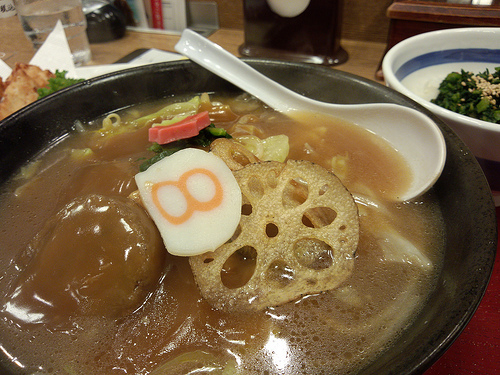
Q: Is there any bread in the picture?
A: Yes, there is a bread.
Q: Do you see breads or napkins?
A: Yes, there is a bread.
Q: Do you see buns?
A: No, there are no buns.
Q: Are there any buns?
A: No, there are no buns.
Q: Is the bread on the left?
A: Yes, the bread is on the left of the image.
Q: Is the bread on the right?
A: No, the bread is on the left of the image.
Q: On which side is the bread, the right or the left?
A: The bread is on the left of the image.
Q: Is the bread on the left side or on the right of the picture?
A: The bread is on the left of the image.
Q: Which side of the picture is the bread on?
A: The bread is on the left of the image.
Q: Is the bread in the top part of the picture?
A: Yes, the bread is in the top of the image.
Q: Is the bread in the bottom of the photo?
A: No, the bread is in the top of the image.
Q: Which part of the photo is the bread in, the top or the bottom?
A: The bread is in the top of the image.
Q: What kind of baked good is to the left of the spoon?
A: The food is a bread.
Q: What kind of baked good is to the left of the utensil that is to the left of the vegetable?
A: The food is a bread.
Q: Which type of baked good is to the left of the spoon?
A: The food is a bread.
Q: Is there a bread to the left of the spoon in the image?
A: Yes, there is a bread to the left of the spoon.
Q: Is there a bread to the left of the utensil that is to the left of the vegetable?
A: Yes, there is a bread to the left of the spoon.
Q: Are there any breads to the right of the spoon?
A: No, the bread is to the left of the spoon.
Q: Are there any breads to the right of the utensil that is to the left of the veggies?
A: No, the bread is to the left of the spoon.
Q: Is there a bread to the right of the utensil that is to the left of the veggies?
A: No, the bread is to the left of the spoon.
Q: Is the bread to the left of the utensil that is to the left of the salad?
A: Yes, the bread is to the left of the spoon.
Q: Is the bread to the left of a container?
A: No, the bread is to the left of the spoon.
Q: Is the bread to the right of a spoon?
A: No, the bread is to the left of a spoon.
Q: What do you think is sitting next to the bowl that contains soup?
A: The bread is sitting next to the bowl.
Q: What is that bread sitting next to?
A: The bread is sitting next to the bowl.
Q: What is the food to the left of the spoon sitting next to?
A: The bread is sitting next to the bowl.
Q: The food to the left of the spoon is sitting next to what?
A: The bread is sitting next to the bowl.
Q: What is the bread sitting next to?
A: The bread is sitting next to the bowl.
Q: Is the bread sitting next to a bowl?
A: Yes, the bread is sitting next to a bowl.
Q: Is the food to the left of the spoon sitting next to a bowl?
A: Yes, the bread is sitting next to a bowl.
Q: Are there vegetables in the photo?
A: Yes, there are vegetables.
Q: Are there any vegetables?
A: Yes, there are vegetables.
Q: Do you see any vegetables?
A: Yes, there are vegetables.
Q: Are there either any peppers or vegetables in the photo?
A: Yes, there are vegetables.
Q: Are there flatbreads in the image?
A: No, there are no flatbreads.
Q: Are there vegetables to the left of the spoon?
A: No, the vegetables are to the right of the spoon.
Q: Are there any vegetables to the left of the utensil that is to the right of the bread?
A: No, the vegetables are to the right of the spoon.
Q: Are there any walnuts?
A: No, there are no walnuts.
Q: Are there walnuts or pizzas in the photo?
A: No, there are no walnuts or pizzas.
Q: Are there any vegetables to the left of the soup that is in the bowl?
A: Yes, there is a vegetable to the left of the soup.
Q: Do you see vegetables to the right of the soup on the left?
A: Yes, there is a vegetable to the right of the soup.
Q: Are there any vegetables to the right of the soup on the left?
A: Yes, there is a vegetable to the right of the soup.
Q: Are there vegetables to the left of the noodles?
A: Yes, there is a vegetable to the left of the noodles.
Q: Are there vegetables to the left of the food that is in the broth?
A: Yes, there is a vegetable to the left of the noodles.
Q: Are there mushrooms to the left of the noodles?
A: No, there is a vegetable to the left of the noodles.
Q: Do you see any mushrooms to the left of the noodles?
A: No, there is a vegetable to the left of the noodles.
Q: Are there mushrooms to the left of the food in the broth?
A: No, there is a vegetable to the left of the noodles.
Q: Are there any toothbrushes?
A: No, there are no toothbrushes.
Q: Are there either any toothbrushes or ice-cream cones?
A: No, there are no toothbrushes or ice-cream cones.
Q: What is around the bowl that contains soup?
A: The ring is around the bowl.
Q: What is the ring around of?
A: The ring is around the bowl.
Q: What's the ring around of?
A: The ring is around the bowl.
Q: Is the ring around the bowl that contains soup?
A: Yes, the ring is around the bowl.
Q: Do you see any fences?
A: No, there are no fences.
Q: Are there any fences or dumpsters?
A: No, there are no fences or dumpsters.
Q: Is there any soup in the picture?
A: Yes, there is soup.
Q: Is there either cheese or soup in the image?
A: Yes, there is soup.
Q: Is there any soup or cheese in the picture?
A: Yes, there is soup.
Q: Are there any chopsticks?
A: No, there are no chopsticks.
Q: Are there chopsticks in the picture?
A: No, there are no chopsticks.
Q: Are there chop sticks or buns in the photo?
A: No, there are no chop sticks or buns.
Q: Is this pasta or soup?
A: This is soup.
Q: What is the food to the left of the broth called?
A: The food is soup.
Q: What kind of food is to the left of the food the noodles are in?
A: The food is soup.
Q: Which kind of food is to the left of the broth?
A: The food is soup.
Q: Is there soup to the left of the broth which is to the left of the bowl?
A: Yes, there is soup to the left of the broth.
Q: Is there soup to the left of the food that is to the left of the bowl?
A: Yes, there is soup to the left of the broth.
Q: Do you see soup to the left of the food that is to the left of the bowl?
A: Yes, there is soup to the left of the broth.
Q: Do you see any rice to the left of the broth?
A: No, there is soup to the left of the broth.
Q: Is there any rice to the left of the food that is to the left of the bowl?
A: No, there is soup to the left of the broth.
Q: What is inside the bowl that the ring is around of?
A: The soup is inside the bowl.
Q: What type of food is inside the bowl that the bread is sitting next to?
A: The food is soup.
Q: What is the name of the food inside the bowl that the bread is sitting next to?
A: The food is soup.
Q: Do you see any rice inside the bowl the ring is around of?
A: No, there is soup inside the bowl.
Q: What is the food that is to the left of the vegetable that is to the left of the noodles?
A: The food is soup.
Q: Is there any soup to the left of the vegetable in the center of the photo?
A: Yes, there is soup to the left of the vegetable.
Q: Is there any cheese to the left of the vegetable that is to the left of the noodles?
A: No, there is soup to the left of the vegetable.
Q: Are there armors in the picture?
A: No, there are no armors.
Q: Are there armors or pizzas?
A: No, there are no armors or pizzas.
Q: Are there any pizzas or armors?
A: No, there are no armors or pizzas.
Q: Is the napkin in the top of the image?
A: Yes, the napkin is in the top of the image.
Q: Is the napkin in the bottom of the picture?
A: No, the napkin is in the top of the image.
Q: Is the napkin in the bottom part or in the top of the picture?
A: The napkin is in the top of the image.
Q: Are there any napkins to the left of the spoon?
A: Yes, there is a napkin to the left of the spoon.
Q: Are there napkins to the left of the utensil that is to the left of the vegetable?
A: Yes, there is a napkin to the left of the spoon.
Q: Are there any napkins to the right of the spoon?
A: No, the napkin is to the left of the spoon.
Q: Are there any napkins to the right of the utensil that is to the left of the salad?
A: No, the napkin is to the left of the spoon.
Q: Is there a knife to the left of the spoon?
A: No, there is a napkin to the left of the spoon.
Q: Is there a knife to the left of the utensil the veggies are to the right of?
A: No, there is a napkin to the left of the spoon.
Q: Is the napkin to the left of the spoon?
A: Yes, the napkin is to the left of the spoon.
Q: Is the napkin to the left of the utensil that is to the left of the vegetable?
A: Yes, the napkin is to the left of the spoon.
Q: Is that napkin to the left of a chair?
A: No, the napkin is to the left of the spoon.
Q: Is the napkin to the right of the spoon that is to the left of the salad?
A: No, the napkin is to the left of the spoon.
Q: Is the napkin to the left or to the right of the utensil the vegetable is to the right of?
A: The napkin is to the left of the spoon.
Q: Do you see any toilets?
A: No, there are no toilets.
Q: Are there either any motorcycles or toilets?
A: No, there are no toilets or motorcycles.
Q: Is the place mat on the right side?
A: Yes, the place mat is on the right of the image.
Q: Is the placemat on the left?
A: No, the placemat is on the right of the image.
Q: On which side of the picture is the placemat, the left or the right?
A: The placemat is on the right of the image.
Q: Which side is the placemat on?
A: The placemat is on the right of the image.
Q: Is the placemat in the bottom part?
A: Yes, the placemat is in the bottom of the image.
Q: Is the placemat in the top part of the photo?
A: No, the placemat is in the bottom of the image.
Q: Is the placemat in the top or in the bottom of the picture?
A: The placemat is in the bottom of the image.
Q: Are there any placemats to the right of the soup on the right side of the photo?
A: Yes, there is a placemat to the right of the soup.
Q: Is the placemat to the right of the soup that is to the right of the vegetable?
A: Yes, the placemat is to the right of the soup.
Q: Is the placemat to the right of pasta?
A: No, the placemat is to the right of the soup.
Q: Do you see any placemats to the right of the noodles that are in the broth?
A: Yes, there is a placemat to the right of the noodles.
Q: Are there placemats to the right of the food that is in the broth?
A: Yes, there is a placemat to the right of the noodles.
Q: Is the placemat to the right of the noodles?
A: Yes, the placemat is to the right of the noodles.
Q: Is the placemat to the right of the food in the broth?
A: Yes, the placemat is to the right of the noodles.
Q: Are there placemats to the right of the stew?
A: Yes, there is a placemat to the right of the stew.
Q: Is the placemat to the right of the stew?
A: Yes, the placemat is to the right of the stew.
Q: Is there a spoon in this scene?
A: Yes, there is a spoon.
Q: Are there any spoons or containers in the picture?
A: Yes, there is a spoon.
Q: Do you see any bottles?
A: No, there are no bottles.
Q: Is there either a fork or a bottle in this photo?
A: No, there are no bottles or forks.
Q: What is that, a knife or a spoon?
A: That is a spoon.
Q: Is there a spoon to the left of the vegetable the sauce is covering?
A: Yes, there is a spoon to the left of the vegetable.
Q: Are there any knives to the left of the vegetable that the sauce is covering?
A: No, there is a spoon to the left of the vegetable.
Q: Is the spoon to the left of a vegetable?
A: Yes, the spoon is to the left of a vegetable.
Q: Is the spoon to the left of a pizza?
A: No, the spoon is to the left of a vegetable.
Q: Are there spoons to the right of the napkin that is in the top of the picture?
A: Yes, there is a spoon to the right of the napkin.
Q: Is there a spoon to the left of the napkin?
A: No, the spoon is to the right of the napkin.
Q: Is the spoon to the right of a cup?
A: No, the spoon is to the right of the napkin.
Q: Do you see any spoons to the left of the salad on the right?
A: Yes, there is a spoon to the left of the salad.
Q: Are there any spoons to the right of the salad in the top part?
A: No, the spoon is to the left of the salad.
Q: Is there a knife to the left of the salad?
A: No, there is a spoon to the left of the salad.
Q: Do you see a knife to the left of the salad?
A: No, there is a spoon to the left of the salad.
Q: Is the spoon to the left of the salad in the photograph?
A: Yes, the spoon is to the left of the salad.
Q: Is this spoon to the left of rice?
A: No, the spoon is to the left of the salad.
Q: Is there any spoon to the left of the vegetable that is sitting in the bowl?
A: Yes, there is a spoon to the left of the vegetable.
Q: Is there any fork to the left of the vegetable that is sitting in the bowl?
A: No, there is a spoon to the left of the vegetable.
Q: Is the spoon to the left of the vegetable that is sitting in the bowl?
A: Yes, the spoon is to the left of the vegetable.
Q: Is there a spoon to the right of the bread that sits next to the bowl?
A: Yes, there is a spoon to the right of the bread.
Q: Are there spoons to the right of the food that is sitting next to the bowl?
A: Yes, there is a spoon to the right of the bread.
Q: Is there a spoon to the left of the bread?
A: No, the spoon is to the right of the bread.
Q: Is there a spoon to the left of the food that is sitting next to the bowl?
A: No, the spoon is to the right of the bread.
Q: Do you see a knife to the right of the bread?
A: No, there is a spoon to the right of the bread.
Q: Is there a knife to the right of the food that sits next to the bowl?
A: No, there is a spoon to the right of the bread.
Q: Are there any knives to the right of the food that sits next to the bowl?
A: No, there is a spoon to the right of the bread.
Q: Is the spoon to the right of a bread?
A: Yes, the spoon is to the right of a bread.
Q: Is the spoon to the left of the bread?
A: No, the spoon is to the right of the bread.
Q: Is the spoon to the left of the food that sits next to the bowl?
A: No, the spoon is to the right of the bread.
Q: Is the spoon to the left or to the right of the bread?
A: The spoon is to the right of the bread.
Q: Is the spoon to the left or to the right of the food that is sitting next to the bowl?
A: The spoon is to the right of the bread.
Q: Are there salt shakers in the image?
A: No, there are no salt shakers.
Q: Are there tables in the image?
A: Yes, there is a table.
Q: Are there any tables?
A: Yes, there is a table.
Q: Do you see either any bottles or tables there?
A: Yes, there is a table.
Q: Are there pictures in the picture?
A: No, there are no pictures.